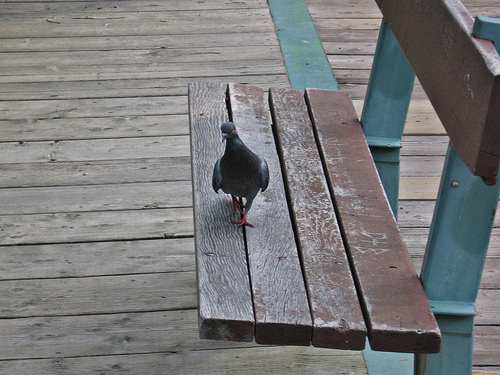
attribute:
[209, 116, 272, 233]
bird — grey, small, walking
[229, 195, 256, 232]
feet — red, orange, sharp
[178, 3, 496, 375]
bench — brown, grey, wooden, blue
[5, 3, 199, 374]
floor — wood, grey, wooden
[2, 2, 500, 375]
photo — clear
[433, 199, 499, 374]
metal — blue, green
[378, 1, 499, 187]
back — dark, dark brown, brown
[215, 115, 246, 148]
head — small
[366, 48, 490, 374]
boards — blue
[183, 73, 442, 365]
wood — brown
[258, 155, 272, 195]
right wing — grey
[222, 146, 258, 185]
chest — gray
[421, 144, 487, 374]
pole — blue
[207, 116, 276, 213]
feathers — black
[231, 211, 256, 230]
leg — orange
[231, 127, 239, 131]
eye — orange